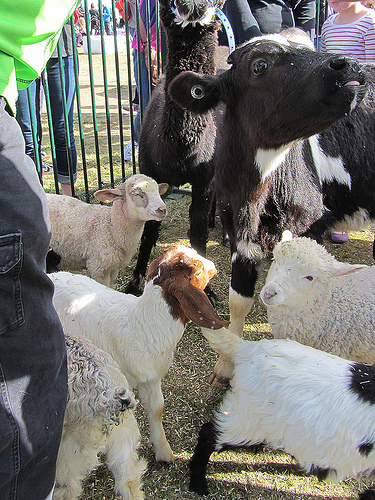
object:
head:
[144, 242, 231, 329]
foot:
[213, 351, 236, 380]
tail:
[198, 324, 253, 365]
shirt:
[0, 1, 83, 121]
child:
[319, 0, 375, 66]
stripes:
[325, 43, 366, 48]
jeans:
[15, 46, 79, 187]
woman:
[13, 17, 82, 197]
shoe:
[329, 229, 350, 243]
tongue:
[343, 79, 360, 86]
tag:
[211, 0, 236, 57]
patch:
[128, 187, 149, 209]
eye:
[133, 193, 144, 199]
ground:
[37, 38, 375, 500]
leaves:
[167, 410, 184, 430]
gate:
[23, 0, 162, 207]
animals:
[122, 0, 235, 298]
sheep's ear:
[328, 259, 371, 281]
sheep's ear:
[91, 186, 126, 204]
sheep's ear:
[166, 276, 231, 330]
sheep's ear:
[157, 182, 169, 195]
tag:
[190, 83, 206, 100]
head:
[258, 227, 369, 308]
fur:
[58, 334, 140, 432]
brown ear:
[167, 275, 232, 331]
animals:
[166, 30, 375, 382]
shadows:
[94, 87, 138, 101]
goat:
[52, 332, 151, 500]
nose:
[324, 55, 363, 75]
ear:
[166, 68, 225, 115]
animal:
[258, 227, 373, 364]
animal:
[186, 322, 375, 498]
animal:
[44, 174, 170, 292]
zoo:
[0, 0, 373, 499]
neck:
[159, 5, 222, 146]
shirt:
[320, 7, 375, 63]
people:
[121, 0, 162, 166]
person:
[0, 0, 83, 499]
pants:
[0, 92, 69, 500]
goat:
[44, 242, 232, 464]